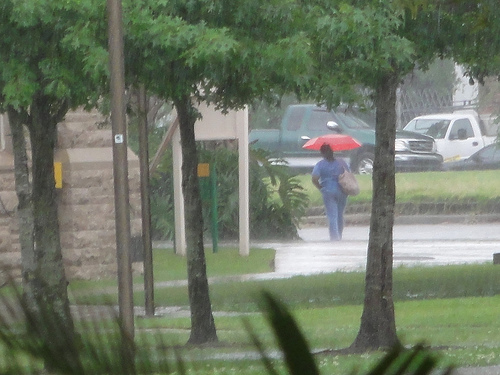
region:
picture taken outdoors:
[6, 6, 494, 368]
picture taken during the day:
[4, 8, 499, 365]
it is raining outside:
[58, 58, 440, 262]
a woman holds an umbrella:
[296, 117, 380, 244]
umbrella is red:
[298, 134, 363, 161]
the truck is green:
[256, 96, 431, 179]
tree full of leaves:
[19, 29, 379, 84]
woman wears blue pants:
[328, 196, 349, 239]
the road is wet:
[422, 218, 465, 252]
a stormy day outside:
[19, 28, 482, 341]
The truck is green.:
[238, 95, 444, 182]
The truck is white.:
[396, 101, 498, 172]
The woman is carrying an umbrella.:
[298, 123, 370, 245]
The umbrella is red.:
[296, 123, 374, 250]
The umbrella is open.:
[295, 117, 373, 253]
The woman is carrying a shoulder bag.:
[296, 125, 374, 248]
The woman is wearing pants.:
[294, 123, 376, 253]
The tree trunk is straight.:
[152, 70, 226, 352]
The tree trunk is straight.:
[26, 20, 78, 374]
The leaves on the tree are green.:
[243, 2, 498, 366]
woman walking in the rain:
[304, 131, 361, 236]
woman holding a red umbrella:
[301, 133, 365, 239]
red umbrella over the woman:
[302, 133, 362, 153]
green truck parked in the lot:
[248, 104, 442, 172]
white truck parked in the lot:
[404, 113, 497, 165]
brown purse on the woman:
[333, 157, 359, 197]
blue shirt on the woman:
[312, 158, 349, 190]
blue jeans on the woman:
[323, 185, 348, 238]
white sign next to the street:
[171, 83, 249, 258]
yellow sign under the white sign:
[190, 161, 220, 251]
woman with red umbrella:
[306, 121, 366, 246]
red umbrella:
[295, 125, 362, 156]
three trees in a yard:
[27, 21, 480, 371]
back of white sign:
[160, 88, 271, 275]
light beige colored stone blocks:
[1, 97, 164, 288]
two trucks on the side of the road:
[250, 86, 488, 172]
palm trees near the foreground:
[3, 280, 458, 371]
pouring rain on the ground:
[11, 5, 457, 345]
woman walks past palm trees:
[131, 127, 317, 247]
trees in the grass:
[1, 18, 488, 362]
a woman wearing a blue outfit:
[304, 135, 369, 250]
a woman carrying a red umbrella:
[300, 123, 373, 245]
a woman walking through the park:
[302, 123, 357, 243]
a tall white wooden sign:
[159, 75, 256, 262]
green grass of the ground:
[427, 295, 487, 329]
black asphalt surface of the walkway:
[426, 219, 482, 250]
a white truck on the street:
[398, 110, 498, 171]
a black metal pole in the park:
[86, 8, 155, 335]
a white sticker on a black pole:
[108, 119, 123, 159]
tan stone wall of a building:
[65, 157, 102, 266]